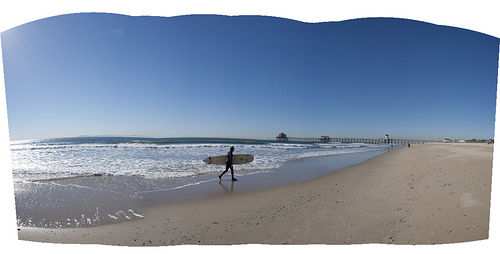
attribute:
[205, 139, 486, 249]
beach — sandy, wet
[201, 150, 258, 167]
surfboard — white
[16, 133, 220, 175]
ocean — water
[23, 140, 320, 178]
waves — small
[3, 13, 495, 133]
skies — blue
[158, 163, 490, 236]
shore — tan, brown